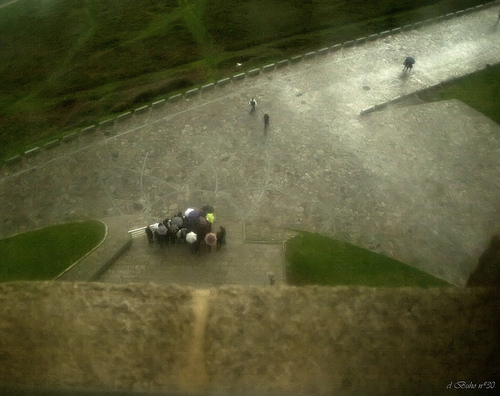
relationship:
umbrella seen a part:
[203, 209, 217, 228] [206, 210, 217, 223]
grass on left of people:
[1, 1, 262, 85] [138, 202, 231, 257]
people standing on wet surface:
[138, 202, 231, 257] [82, 132, 284, 283]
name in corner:
[445, 374, 500, 393] [430, 352, 499, 393]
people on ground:
[138, 202, 231, 257] [81, 79, 499, 246]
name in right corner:
[445, 374, 500, 393] [430, 352, 499, 393]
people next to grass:
[138, 202, 231, 257] [1, 1, 262, 85]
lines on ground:
[89, 132, 270, 201] [81, 79, 499, 246]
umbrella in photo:
[183, 209, 200, 230] [3, 4, 497, 386]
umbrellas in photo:
[138, 202, 231, 257] [3, 4, 497, 386]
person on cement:
[263, 113, 270, 126] [81, 79, 499, 246]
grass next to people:
[1, 1, 262, 85] [138, 202, 231, 257]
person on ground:
[263, 113, 270, 126] [81, 79, 499, 246]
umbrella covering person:
[203, 209, 217, 228] [205, 219, 215, 232]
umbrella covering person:
[154, 223, 170, 239] [157, 233, 168, 243]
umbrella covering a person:
[199, 202, 215, 213] [263, 113, 270, 126]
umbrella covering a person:
[402, 56, 416, 67] [402, 64, 410, 71]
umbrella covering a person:
[166, 220, 178, 235] [165, 231, 177, 242]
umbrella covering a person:
[175, 224, 187, 235] [179, 235, 188, 240]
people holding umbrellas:
[138, 202, 231, 257] [145, 201, 220, 248]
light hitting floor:
[418, 31, 493, 72] [0, 0, 500, 285]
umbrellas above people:
[138, 202, 231, 257] [145, 199, 227, 259]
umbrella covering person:
[202, 231, 219, 247] [195, 233, 217, 256]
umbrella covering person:
[181, 202, 197, 219] [180, 206, 192, 228]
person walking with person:
[259, 114, 280, 133] [240, 88, 261, 108]